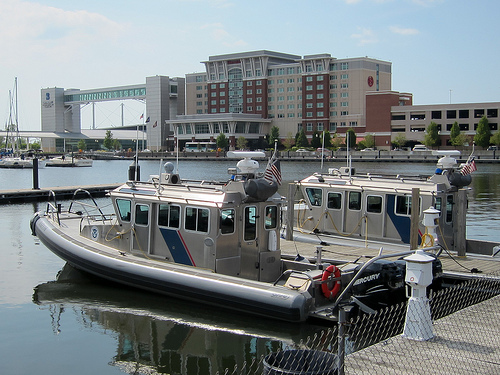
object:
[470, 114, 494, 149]
tree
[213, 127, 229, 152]
tree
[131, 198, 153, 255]
door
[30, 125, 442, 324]
boat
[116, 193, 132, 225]
windows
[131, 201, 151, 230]
windows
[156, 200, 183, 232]
windows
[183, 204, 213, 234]
windows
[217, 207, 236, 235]
windows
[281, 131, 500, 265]
boat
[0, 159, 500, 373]
water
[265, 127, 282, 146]
tree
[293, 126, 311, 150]
tree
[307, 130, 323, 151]
tree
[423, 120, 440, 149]
tree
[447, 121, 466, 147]
tree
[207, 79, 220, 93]
windows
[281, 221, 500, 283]
boardwalk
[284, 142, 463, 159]
parking lot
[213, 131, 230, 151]
tree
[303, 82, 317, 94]
windows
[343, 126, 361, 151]
tree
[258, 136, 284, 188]
flag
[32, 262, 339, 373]
reflection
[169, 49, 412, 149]
building